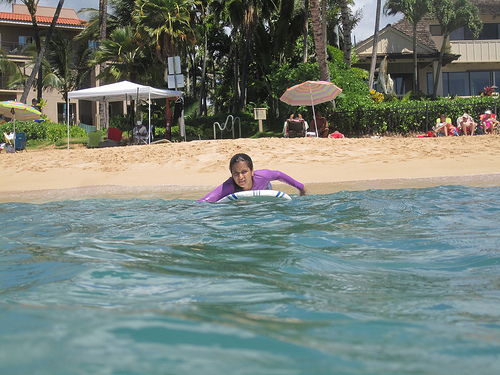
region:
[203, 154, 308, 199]
woman with purple wetsuit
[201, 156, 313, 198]
surfboarder in purple wetsuit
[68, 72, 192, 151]
big white awning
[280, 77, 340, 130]
orange and blue umbrella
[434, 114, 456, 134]
woman with green t-shirt sitting on seashore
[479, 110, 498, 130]
woman sitting on pink chair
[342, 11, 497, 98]
big brown and beige house in the right side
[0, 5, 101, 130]
big orange and beige house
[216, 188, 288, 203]
blue and white surfboard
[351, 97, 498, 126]
green bushes in the back of people sitting on seashore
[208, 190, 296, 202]
Blue and white surfboard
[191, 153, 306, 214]
Surfer in purple swimsuit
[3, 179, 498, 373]
Beautiful clear blue water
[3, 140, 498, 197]
Sand at the beach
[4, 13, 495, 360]
A beautiful vibrant beach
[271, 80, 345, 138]
Beautiful colorful pink umbrella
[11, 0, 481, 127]
Palm trees behind the beach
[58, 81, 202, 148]
White cover with man under it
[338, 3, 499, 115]
Beautiful house in the backgroun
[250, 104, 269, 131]
Post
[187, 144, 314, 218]
A woman wearing a purple wetsuit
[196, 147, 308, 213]
A woman swimming on a white surfboard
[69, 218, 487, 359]
Clear blue wavy ocean water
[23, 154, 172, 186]
A brown sandy ground surface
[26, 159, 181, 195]
A brown sandy beach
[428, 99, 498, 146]
A group of people sitting on the beach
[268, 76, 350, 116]
A striped beach umbrella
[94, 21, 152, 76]
Green palm tree leaves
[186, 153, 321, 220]
A woman with brown hair swimming in the ocean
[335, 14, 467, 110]
The entrance to a building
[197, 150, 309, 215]
a woman on her surfboard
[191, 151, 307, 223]
a woman wearing a purple wetsuit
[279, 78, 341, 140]
a beach umbrella on the beach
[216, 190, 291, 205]
a white surfboard the kid is using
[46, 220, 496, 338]
a body of water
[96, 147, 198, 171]
a sandy ground with traces of footprints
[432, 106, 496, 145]
a people sitting on a folding chair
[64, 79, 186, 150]
a white canopy tent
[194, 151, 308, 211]
a surfer in the water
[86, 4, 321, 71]
coconut trees in the background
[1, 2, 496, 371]
the girl is at the beach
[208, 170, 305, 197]
the girl has a purple suit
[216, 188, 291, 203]
the girl is on a surf board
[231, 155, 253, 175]
the girl has hair pulled back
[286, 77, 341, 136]
the umbrella has stripes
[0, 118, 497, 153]
people are on the beach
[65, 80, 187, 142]
a person under a canopy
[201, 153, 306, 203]
the person is in the water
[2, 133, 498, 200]
the sand is brown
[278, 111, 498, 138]
people are sitting in chairs